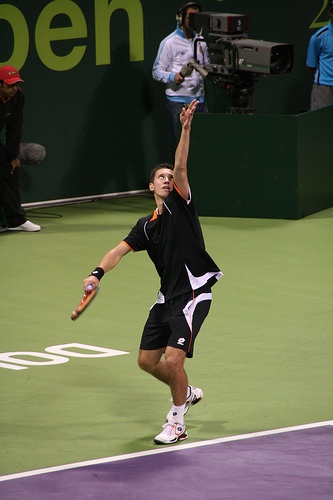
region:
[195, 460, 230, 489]
the lawn is purple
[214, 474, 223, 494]
the lawn is purple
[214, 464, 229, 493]
the lawn is purple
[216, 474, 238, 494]
the lawn is purple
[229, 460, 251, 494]
the lawn is purple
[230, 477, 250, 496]
the lawn is purple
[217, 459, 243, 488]
the lawn is purple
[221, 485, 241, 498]
the lawn is purple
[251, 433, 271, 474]
the lawn is purple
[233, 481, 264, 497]
the lawn is purple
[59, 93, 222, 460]
a tennis player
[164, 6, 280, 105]
a cameraman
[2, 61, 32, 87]
man wearing a red cap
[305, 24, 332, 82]
man wearing a blue shirt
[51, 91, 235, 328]
tennis player about to hit a ball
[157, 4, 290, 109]
cameraman filming a tennis match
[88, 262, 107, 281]
a black wristband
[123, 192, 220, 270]
black shirt with white and orange lines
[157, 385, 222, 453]
man wearing white sneakers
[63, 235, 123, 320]
man holding a tennis racket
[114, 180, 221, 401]
A man in black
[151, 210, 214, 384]
A man in black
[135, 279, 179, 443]
A man in black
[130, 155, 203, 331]
A man in black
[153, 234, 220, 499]
A man in black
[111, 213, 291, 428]
A man in black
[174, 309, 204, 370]
A man in black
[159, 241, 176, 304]
A man in black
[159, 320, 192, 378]
A man in black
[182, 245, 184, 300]
A man in black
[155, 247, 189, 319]
A man in black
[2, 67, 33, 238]
man wearing red baseball hat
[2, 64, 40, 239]
man wearing black sweat suit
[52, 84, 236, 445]
man playing tennis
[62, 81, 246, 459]
man holding tennis racket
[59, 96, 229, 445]
man wearing black shirt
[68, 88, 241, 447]
man wearing black shorts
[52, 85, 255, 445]
man wearing black wrist band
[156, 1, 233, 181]
man wearing ear phones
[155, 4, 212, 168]
man wearing white and blue jacket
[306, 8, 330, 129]
man wearing blue shirt